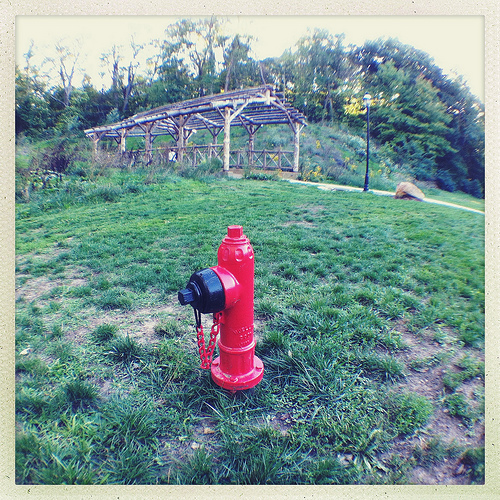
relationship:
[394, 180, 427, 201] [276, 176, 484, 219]
rock next to path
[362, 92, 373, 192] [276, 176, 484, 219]
lamp post next to path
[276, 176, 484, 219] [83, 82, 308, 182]
path next to bridge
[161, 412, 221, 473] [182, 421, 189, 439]
dirt has grass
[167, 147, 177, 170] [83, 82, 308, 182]
person walking on bridge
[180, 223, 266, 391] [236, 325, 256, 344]
hydrant has imprint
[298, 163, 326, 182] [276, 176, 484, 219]
bush next to path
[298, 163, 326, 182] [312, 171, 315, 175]
bush has flower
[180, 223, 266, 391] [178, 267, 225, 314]
hydrant has cap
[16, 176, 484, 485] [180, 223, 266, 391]
field has hydrant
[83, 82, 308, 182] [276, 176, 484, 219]
bridge next to path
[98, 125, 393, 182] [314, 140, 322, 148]
hill has flower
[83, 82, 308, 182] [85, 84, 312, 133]
bridge has roof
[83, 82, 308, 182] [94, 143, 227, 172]
bridge has guardrail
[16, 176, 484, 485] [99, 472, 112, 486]
field has grass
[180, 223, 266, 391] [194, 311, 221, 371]
hydrant has chain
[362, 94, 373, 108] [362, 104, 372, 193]
lamp has lamp post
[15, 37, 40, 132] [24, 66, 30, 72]
tree has leaf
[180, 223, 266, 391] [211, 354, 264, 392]
hydrant has base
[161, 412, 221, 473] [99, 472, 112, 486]
dirt has grass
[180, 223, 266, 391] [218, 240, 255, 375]
hydrant has tank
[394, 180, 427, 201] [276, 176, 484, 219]
rock in front of path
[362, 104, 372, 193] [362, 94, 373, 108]
lamp post has lamp